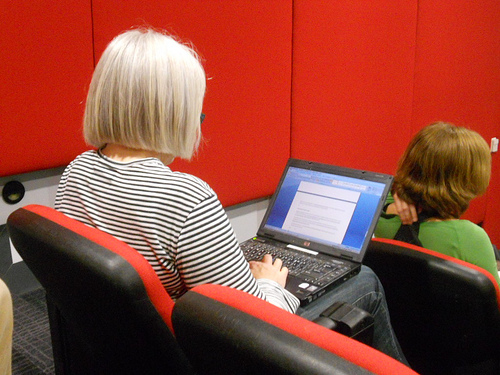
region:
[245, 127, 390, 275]
the computer is on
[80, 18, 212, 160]
the hair is white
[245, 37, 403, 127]
the wall is red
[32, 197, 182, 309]
the seat is red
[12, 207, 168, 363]
the back is black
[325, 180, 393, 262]
the color is blue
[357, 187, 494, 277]
the shirt is green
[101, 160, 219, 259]
the shirt is stripped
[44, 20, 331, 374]
the woman is sitting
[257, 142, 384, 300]
the computer is black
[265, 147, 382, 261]
the screen is on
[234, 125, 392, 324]
the computer is a laptop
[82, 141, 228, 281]
the shirt is black and white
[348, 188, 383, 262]
the color is blue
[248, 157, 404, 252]
computer screen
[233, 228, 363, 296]
laptop computer keyboard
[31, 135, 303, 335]
a long sleeved horizontal striped shirt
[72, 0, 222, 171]
a woman's gray hair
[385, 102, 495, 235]
a woman's brown hair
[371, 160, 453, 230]
a hand that is scratching a back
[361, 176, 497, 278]
a green shirt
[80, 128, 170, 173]
a woman's neck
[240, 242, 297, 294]
a hand operating a trackpad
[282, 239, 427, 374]
jeans being worn around a woman's leg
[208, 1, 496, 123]
A red wall.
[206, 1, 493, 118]
A red padded wall.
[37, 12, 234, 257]
Woman with blonde hair.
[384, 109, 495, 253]
Person with red, short hair.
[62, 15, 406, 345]
Woman holding a laptop.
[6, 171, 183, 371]
Black and red chair.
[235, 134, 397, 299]
An open laptop computer.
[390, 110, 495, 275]
A person in a green shirt.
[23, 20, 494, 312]
Two people sitting down in a room.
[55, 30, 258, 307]
Woman in a striped shirt.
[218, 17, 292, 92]
this is the wall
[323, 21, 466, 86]
the wall is orange in color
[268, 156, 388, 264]
this is a laptop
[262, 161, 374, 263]
the laptop is black in color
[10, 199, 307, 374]
these are chairs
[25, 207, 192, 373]
the chairs are black and orange in color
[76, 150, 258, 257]
this is a person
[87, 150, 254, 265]
the gal is wearing black and white stripe shirt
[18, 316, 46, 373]
this is the floor of the room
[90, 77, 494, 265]
there are two people in the room